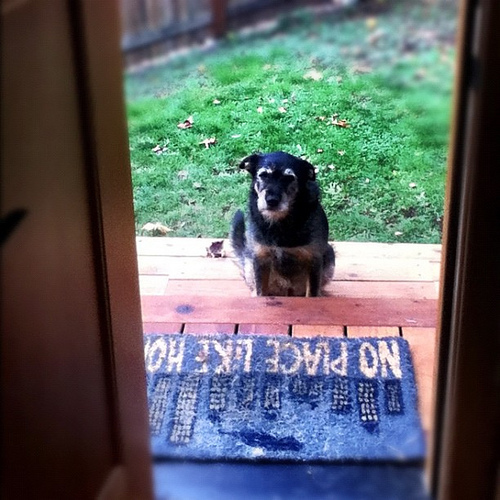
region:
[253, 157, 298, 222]
The dog's face is black and brown.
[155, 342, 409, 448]
The rug is blue and white.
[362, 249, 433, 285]
The floor is made of wood.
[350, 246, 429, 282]
The floor is brown in color.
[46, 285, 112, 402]
The wall is brown in color.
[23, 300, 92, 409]
The wall is made of wood.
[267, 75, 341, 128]
The grass in the background is green.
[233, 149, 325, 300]
The dog is sitting on the porch.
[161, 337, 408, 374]
The writing on the rug is in white.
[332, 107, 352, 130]
The leaf on the grass is brown.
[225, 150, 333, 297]
brown and black dog sitting on wood deck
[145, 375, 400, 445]
skyscrapers and lights on doormat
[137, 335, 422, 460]
mat in front of door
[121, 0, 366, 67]
wood fence surrounding yard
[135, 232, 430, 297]
wooden planks on deck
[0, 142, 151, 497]
opened door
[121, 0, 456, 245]
grass in yard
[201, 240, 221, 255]
brown leaf on deck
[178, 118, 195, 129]
brown leaf in yard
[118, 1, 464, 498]
door opening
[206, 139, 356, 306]
A dog sitting on the step looking sad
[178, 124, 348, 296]
He wants to come in the house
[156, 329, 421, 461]
A welcome mat on the top step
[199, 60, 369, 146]
The leaves are falling from the trees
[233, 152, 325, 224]
The dog is black and brown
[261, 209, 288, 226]
he has a beard growing on his chin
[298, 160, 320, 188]
One ear is down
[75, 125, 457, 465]
The door to the home is open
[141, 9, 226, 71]
The fence is made of wood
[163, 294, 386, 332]
The steps are made of wood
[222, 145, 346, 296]
dog sitting on door step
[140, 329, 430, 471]
door mat on the door step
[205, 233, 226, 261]
leaf on the door step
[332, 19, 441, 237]
grass area in lawn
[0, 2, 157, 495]
part of door to outside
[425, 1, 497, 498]
additional part of door to outside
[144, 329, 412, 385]
writing on the mat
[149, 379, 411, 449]
pictures of buildings on the mat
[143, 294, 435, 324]
wooden plank on door step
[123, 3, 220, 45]
fence enclosing the outside area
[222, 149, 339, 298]
a dog on a step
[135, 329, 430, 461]
a doormat on a step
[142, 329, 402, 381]
white letters on the mat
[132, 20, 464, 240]
brown leaves on the grass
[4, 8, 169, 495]
the door is brown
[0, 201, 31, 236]
the door handle is dark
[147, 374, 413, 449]
building drawings on the mat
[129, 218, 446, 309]
a step on the porch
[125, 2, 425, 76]
a fence behind the grass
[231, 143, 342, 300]
the dog is black and brown